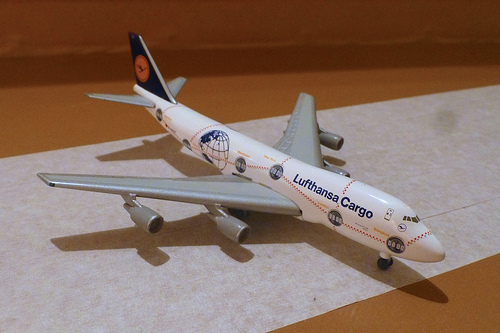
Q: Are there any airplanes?
A: Yes, there is an airplane.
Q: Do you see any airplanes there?
A: Yes, there is an airplane.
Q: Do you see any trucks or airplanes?
A: Yes, there is an airplane.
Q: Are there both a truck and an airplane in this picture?
A: No, there is an airplane but no trucks.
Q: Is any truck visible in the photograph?
A: No, there are no trucks.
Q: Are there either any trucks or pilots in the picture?
A: No, there are no trucks or pilots.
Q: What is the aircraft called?
A: The aircraft is an airplane.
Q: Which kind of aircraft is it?
A: The aircraft is an airplane.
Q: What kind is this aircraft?
A: This is an airplane.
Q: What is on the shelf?
A: The airplane is on the shelf.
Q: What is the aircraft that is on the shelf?
A: The aircraft is an airplane.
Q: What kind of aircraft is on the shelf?
A: The aircraft is an airplane.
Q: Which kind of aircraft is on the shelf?
A: The aircraft is an airplane.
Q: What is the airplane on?
A: The airplane is on the shelf.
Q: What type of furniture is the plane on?
A: The plane is on the shelf.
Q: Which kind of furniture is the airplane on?
A: The plane is on the shelf.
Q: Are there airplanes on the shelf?
A: Yes, there is an airplane on the shelf.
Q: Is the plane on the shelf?
A: Yes, the plane is on the shelf.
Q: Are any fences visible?
A: No, there are no fences.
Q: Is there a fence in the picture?
A: No, there are no fences.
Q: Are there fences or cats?
A: No, there are no fences or cats.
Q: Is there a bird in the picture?
A: No, there are no birds.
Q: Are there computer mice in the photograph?
A: No, there are no computer mice.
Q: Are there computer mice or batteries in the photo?
A: No, there are no computer mice or batteries.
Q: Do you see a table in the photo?
A: Yes, there is a table.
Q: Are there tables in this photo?
A: Yes, there is a table.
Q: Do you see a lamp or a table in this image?
A: Yes, there is a table.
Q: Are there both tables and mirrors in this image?
A: No, there is a table but no mirrors.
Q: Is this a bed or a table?
A: This is a table.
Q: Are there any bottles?
A: No, there are no bottles.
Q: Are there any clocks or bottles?
A: No, there are no bottles or clocks.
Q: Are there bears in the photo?
A: No, there are no bears.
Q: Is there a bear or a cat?
A: No, there are no bears or cats.